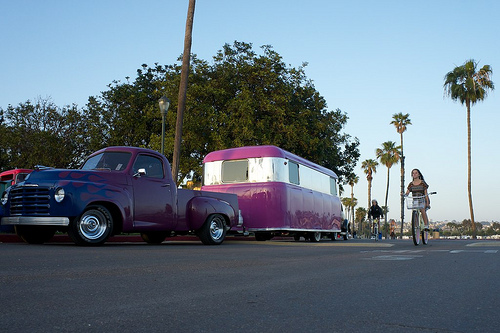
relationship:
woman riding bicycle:
[412, 163, 432, 217] [403, 189, 438, 246]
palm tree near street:
[444, 59, 493, 237] [6, 234, 494, 324]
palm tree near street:
[396, 115, 410, 239] [6, 234, 494, 324]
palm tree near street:
[380, 143, 395, 235] [6, 234, 494, 324]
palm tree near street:
[362, 154, 383, 238] [6, 234, 494, 324]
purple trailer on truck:
[205, 146, 348, 239] [7, 146, 241, 245]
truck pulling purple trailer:
[7, 146, 241, 245] [205, 146, 348, 239]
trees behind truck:
[5, 43, 351, 241] [7, 146, 241, 245]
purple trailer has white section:
[205, 146, 348, 239] [205, 154, 343, 195]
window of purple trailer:
[217, 155, 254, 185] [205, 146, 348, 239]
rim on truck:
[76, 211, 110, 237] [7, 146, 241, 245]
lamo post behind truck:
[158, 98, 169, 150] [7, 146, 241, 245]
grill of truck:
[11, 187, 51, 217] [7, 146, 241, 245]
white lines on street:
[361, 242, 497, 262] [6, 234, 494, 324]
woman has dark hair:
[412, 163, 432, 217] [412, 168, 426, 183]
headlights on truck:
[2, 187, 67, 207] [7, 146, 241, 245]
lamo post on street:
[158, 94, 170, 154] [6, 234, 494, 324]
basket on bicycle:
[404, 191, 440, 211] [403, 189, 438, 246]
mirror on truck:
[132, 164, 149, 176] [7, 146, 241, 245]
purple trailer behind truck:
[205, 146, 348, 239] [7, 146, 241, 245]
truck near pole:
[7, 146, 241, 245] [170, 0, 200, 181]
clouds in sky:
[370, 185, 496, 224] [6, 5, 492, 101]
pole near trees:
[170, 0, 200, 181] [5, 43, 351, 241]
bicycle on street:
[403, 189, 438, 246] [6, 234, 494, 324]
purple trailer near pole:
[205, 146, 348, 239] [170, 0, 200, 181]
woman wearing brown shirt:
[412, 163, 432, 217] [410, 181, 428, 195]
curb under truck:
[10, 232, 250, 243] [7, 146, 241, 245]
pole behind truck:
[170, 0, 200, 181] [7, 146, 241, 245]